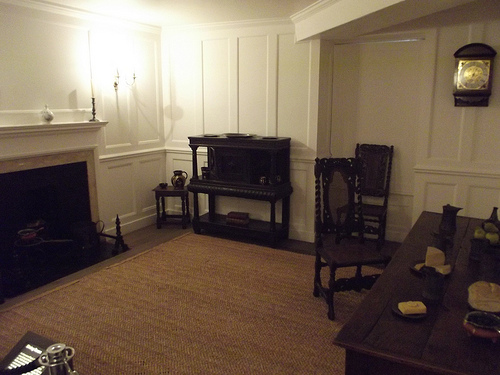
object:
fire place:
[0, 185, 66, 242]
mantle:
[0, 107, 111, 139]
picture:
[0, 0, 500, 375]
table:
[152, 186, 190, 230]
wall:
[415, 0, 500, 165]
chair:
[311, 157, 392, 321]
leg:
[313, 252, 323, 298]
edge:
[330, 328, 355, 349]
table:
[331, 210, 500, 375]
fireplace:
[0, 161, 131, 305]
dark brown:
[335, 248, 364, 261]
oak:
[315, 241, 334, 267]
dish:
[391, 293, 434, 318]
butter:
[398, 300, 428, 314]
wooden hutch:
[185, 133, 292, 247]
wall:
[164, 19, 316, 242]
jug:
[171, 170, 189, 190]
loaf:
[467, 280, 500, 313]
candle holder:
[89, 98, 100, 122]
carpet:
[0, 231, 383, 375]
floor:
[0, 212, 404, 375]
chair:
[335, 142, 394, 253]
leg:
[325, 263, 335, 319]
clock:
[451, 42, 497, 107]